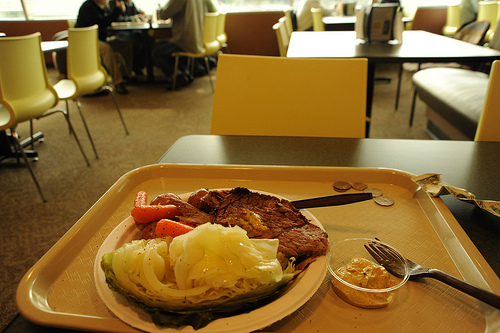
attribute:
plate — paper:
[93, 187, 333, 332]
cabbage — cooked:
[99, 221, 301, 331]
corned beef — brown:
[172, 187, 330, 274]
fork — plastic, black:
[365, 236, 500, 310]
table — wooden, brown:
[2, 134, 499, 333]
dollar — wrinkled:
[412, 171, 500, 215]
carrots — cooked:
[132, 191, 194, 238]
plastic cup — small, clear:
[326, 236, 411, 308]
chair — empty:
[213, 55, 368, 137]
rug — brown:
[1, 62, 435, 330]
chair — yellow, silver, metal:
[50, 23, 130, 160]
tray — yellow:
[11, 157, 498, 331]